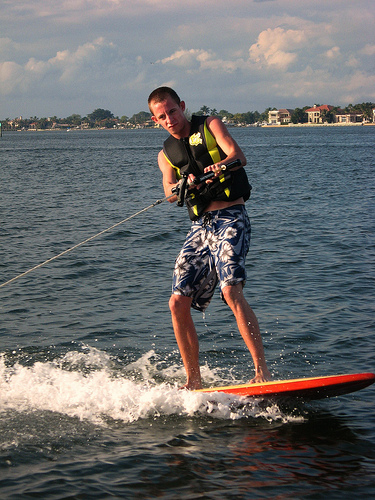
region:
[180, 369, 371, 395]
part of a surfboard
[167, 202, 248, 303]
a boy's blue and white shorts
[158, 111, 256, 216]
a black and yellow life jacket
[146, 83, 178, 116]
a boy's brown hair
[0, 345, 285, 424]
a white wave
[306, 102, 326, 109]
the roof of a building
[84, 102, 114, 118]
a large green tree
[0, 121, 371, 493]
a large body of water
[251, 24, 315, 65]
a large white cloud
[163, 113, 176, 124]
the nose of a boy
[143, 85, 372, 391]
A male on a board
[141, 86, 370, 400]
A man on a board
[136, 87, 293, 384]
A male in a life vest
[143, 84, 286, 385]
A man in a life vest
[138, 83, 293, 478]
A man on the water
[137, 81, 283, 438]
A male on the water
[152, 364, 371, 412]
An orange and white board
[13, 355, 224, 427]
Waves in the water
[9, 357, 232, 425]
White waves in the lake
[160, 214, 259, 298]
The swim trunks of the man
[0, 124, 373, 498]
Expanse of clear water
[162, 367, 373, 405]
Orange surfboard partially hidden in water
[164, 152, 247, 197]
Hands gripping firmly on handlebars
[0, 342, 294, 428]
White bubbling splash of water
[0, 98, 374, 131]
Shoreline with buildings and vegetation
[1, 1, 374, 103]
Sky filled with dark, thick clouds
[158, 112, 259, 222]
Black colored lifejacket with stripes of yellow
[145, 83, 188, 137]
Head with low cut hair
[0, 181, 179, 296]
Thin, tight grey rope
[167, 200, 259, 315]
Loose fitting pair of shorts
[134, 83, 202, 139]
boy has short hair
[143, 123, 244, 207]
boy has yellow jacket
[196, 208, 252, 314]
blue and white shorts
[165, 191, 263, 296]
boy's shorts are floral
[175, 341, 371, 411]
yellow and orange wakeboard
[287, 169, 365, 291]
water around boy is blue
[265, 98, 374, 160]
buildings are on shore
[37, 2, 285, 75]
sky has many clouds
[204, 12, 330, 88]
clouds are thick and puffy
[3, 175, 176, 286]
boy holds grey cord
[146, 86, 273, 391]
the man on the water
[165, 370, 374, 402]
the board in the water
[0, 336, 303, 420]
the white water splashing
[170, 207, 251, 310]
the man's surf shorts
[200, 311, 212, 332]
the water dripping from the man's shorts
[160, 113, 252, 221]
the vest on the man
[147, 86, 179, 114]
the hair on the man's head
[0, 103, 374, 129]
the buildings in the distance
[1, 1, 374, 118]
the clouds in the sky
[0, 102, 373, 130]
the trees in the distance